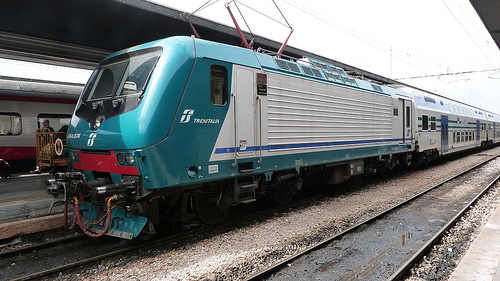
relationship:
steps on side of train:
[231, 177, 258, 204] [47, 30, 487, 211]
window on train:
[208, 61, 228, 111] [47, 30, 487, 211]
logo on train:
[179, 104, 229, 130] [75, 35, 451, 207]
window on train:
[78, 46, 163, 102] [38, 21, 498, 194]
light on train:
[141, 45, 168, 129] [47, 30, 487, 211]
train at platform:
[47, 30, 487, 211] [8, 148, 85, 226]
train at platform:
[47, 30, 487, 211] [9, 148, 94, 245]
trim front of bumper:
[57, 138, 145, 184] [40, 167, 158, 219]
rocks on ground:
[60, 143, 499, 279] [0, 145, 498, 277]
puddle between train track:
[391, 231, 422, 248] [246, 155, 500, 281]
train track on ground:
[246, 155, 497, 279] [0, 145, 498, 277]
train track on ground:
[2, 202, 269, 280] [0, 145, 498, 277]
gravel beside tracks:
[199, 229, 289, 249] [282, 242, 452, 279]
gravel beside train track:
[199, 229, 289, 249] [2, 202, 269, 280]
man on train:
[39, 119, 55, 133] [47, 30, 487, 211]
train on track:
[47, 30, 487, 211] [1, 211, 119, 274]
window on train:
[419, 111, 432, 133] [47, 30, 487, 211]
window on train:
[428, 115, 438, 129] [61, 50, 420, 206]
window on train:
[431, 115, 437, 130] [47, 30, 487, 211]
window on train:
[78, 46, 163, 102] [47, 30, 487, 211]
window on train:
[422, 114, 428, 130] [47, 30, 487, 211]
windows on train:
[453, 131, 475, 144] [47, 30, 487, 211]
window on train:
[257, 73, 267, 93] [47, 30, 487, 211]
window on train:
[209, 65, 227, 107] [47, 30, 487, 211]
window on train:
[0, 110, 22, 135] [47, 30, 487, 211]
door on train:
[235, 65, 259, 155] [13, 30, 499, 242]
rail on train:
[256, 89, 266, 169] [47, 30, 487, 211]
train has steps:
[47, 30, 487, 211] [231, 177, 258, 204]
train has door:
[47, 30, 487, 211] [233, 66, 255, 155]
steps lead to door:
[231, 177, 258, 204] [233, 66, 255, 155]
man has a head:
[39, 117, 56, 132] [38, 117, 50, 127]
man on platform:
[39, 117, 56, 132] [0, 69, 73, 174]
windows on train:
[450, 126, 479, 148] [47, 30, 487, 211]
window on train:
[78, 47, 158, 106] [47, 30, 487, 211]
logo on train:
[179, 104, 229, 130] [47, 30, 487, 211]